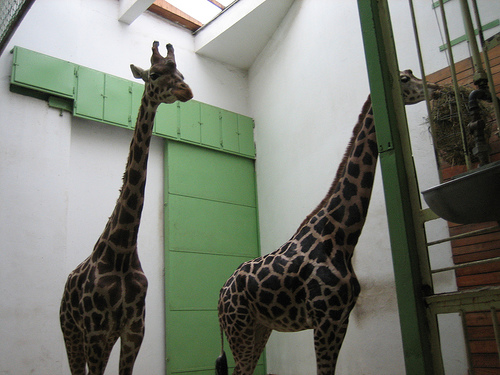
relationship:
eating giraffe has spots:
[215, 69, 441, 374] [283, 243, 335, 301]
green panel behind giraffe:
[163, 191, 260, 258] [58, 41, 192, 375]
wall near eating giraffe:
[254, 0, 497, 365] [215, 69, 441, 374]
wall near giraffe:
[254, 0, 497, 365] [58, 41, 192, 375]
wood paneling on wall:
[458, 308, 498, 373] [440, 219, 497, 283]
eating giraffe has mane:
[215, 69, 441, 374] [289, 87, 374, 245]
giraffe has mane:
[58, 41, 192, 375] [92, 80, 149, 253]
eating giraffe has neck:
[215, 69, 441, 374] [327, 116, 391, 246]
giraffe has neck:
[58, 41, 192, 375] [111, 101, 162, 239]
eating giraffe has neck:
[215, 69, 441, 374] [285, 81, 387, 253]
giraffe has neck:
[58, 41, 192, 375] [86, 93, 161, 268]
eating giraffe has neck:
[215, 69, 441, 374] [312, 96, 389, 258]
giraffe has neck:
[58, 41, 192, 375] [112, 98, 154, 244]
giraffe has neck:
[58, 41, 192, 375] [117, 112, 162, 247]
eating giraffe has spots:
[215, 69, 441, 374] [266, 262, 311, 302]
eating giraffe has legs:
[215, 69, 441, 374] [313, 315, 348, 371]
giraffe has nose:
[47, 36, 181, 373] [168, 80, 195, 107]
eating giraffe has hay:
[215, 69, 441, 374] [432, 100, 487, 167]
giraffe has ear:
[47, 36, 181, 373] [119, 57, 151, 87]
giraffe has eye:
[58, 41, 192, 375] [147, 72, 161, 79]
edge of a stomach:
[260, 319, 316, 340] [242, 252, 312, 332]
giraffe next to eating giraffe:
[58, 41, 192, 375] [215, 69, 441, 374]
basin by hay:
[421, 160, 498, 224] [426, 80, 493, 164]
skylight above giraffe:
[145, 0, 240, 32] [58, 41, 192, 375]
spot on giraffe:
[132, 144, 146, 162] [58, 41, 192, 375]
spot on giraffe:
[340, 177, 358, 199] [267, 73, 362, 350]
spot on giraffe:
[308, 238, 335, 264] [58, 41, 192, 375]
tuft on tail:
[208, 346, 228, 373] [203, 303, 244, 374]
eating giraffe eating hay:
[215, 69, 441, 374] [419, 82, 487, 165]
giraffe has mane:
[58, 41, 192, 375] [110, 78, 138, 226]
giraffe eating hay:
[58, 41, 192, 375] [424, 77, 491, 173]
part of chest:
[326, 249, 363, 302] [324, 250, 364, 327]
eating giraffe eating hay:
[215, 69, 441, 374] [422, 72, 499, 160]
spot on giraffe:
[294, 229, 319, 255] [192, 35, 444, 373]